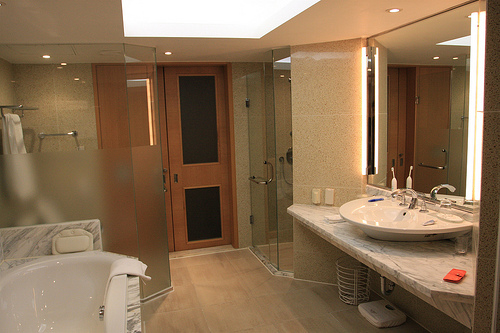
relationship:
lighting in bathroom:
[351, 46, 383, 182] [16, 44, 494, 188]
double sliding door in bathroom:
[65, 35, 187, 299] [16, 44, 494, 188]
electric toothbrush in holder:
[389, 165, 398, 198] [380, 167, 407, 211]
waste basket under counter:
[328, 258, 375, 310] [306, 199, 458, 295]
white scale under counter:
[355, 293, 409, 330] [306, 199, 458, 295]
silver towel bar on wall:
[240, 159, 277, 195] [242, 155, 311, 197]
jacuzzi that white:
[32, 249, 132, 329] [14, 273, 112, 325]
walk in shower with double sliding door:
[27, 87, 171, 224] [122, 42, 173, 301]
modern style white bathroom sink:
[287, 170, 465, 253] [348, 190, 445, 246]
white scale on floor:
[355, 293, 409, 330] [218, 266, 295, 318]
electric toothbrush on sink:
[387, 163, 397, 198] [348, 190, 445, 246]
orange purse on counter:
[432, 264, 469, 292] [306, 199, 458, 295]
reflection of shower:
[381, 41, 466, 168] [57, 63, 147, 165]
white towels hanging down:
[2, 112, 23, 196] [1, 98, 32, 202]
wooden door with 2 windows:
[166, 72, 236, 238] [117, 75, 223, 162]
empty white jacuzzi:
[32, 249, 132, 329] [0, 249, 133, 333]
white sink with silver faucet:
[348, 190, 445, 246] [390, 188, 430, 213]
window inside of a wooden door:
[115, 88, 169, 154] [166, 67, 237, 250]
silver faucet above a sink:
[372, 184, 440, 213] [348, 190, 445, 246]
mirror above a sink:
[381, 41, 466, 168] [348, 190, 445, 246]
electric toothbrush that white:
[387, 163, 397, 198] [14, 273, 112, 325]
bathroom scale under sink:
[355, 293, 409, 330] [348, 190, 445, 246]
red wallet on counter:
[441, 255, 462, 295] [306, 199, 458, 295]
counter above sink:
[306, 199, 458, 295] [348, 190, 445, 246]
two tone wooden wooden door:
[117, 75, 223, 162] [166, 67, 237, 250]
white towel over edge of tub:
[86, 257, 176, 291] [14, 273, 112, 325]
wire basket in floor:
[328, 258, 375, 310] [142, 243, 430, 331]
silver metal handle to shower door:
[245, 161, 281, 183] [239, 151, 288, 189]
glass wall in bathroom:
[54, 75, 130, 135] [16, 44, 494, 188]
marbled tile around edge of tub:
[168, 286, 248, 333] [14, 273, 112, 325]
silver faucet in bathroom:
[372, 184, 440, 213] [16, 44, 494, 188]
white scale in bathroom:
[355, 293, 409, 330] [16, 44, 494, 188]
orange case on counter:
[432, 264, 469, 292] [306, 199, 458, 295]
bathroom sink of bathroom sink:
[340, 190, 473, 246] [340, 190, 473, 246]